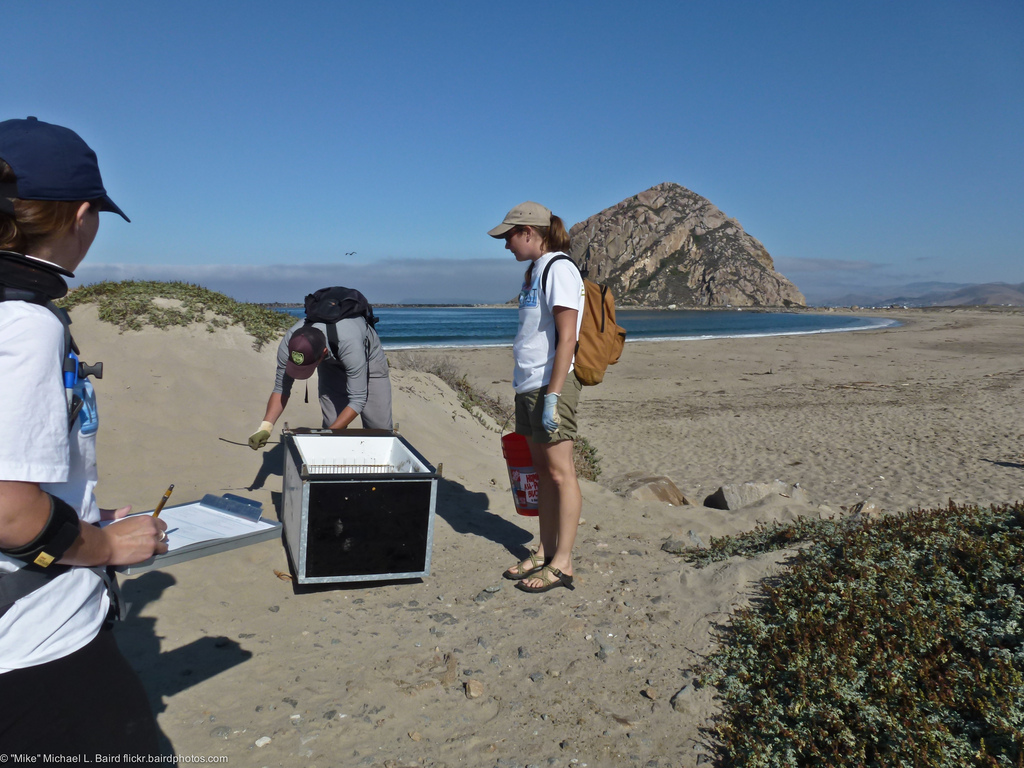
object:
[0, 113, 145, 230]
hat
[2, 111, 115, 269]
head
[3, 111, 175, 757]
woman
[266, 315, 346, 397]
hat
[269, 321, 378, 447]
person's head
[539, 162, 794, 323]
rock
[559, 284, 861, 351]
water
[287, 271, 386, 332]
backpack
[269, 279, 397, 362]
man's back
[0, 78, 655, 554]
people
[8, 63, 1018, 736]
beach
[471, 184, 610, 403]
girl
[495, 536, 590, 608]
sandals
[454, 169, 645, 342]
girl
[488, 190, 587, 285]
cap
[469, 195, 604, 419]
girl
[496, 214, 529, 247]
glasses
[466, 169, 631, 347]
girl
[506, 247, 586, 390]
shirt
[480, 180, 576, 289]
girl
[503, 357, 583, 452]
shorts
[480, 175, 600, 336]
girl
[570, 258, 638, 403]
backpack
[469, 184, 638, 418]
girl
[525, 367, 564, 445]
gloves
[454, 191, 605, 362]
girl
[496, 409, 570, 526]
bucket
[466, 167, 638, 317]
girl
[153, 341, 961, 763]
beach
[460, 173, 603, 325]
woman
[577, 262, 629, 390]
bucket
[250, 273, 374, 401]
man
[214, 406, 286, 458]
samples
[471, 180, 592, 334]
woman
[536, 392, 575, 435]
gloves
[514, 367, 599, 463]
hands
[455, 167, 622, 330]
woman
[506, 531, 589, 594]
sandals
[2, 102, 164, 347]
person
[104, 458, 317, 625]
clipboard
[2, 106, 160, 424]
person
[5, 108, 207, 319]
hat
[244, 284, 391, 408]
man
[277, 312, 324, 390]
hat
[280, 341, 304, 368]
logo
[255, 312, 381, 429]
man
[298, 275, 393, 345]
backpack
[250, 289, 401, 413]
man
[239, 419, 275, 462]
gloves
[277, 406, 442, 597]
container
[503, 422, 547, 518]
red bucket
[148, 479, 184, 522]
pencil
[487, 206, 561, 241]
brown cap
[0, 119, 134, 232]
blue cap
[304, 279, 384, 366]
black backpack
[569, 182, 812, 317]
large rock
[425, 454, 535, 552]
shadow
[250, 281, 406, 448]
man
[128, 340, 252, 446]
tan sand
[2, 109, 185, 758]
man